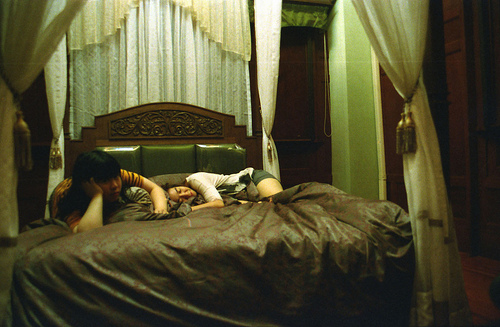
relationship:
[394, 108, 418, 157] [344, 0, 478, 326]
tassel on curtain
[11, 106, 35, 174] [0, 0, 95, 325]
tassel on curtain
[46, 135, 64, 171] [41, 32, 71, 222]
tassel on curtain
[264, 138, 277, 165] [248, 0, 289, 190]
tassel on curtain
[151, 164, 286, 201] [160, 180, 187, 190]
woman has hair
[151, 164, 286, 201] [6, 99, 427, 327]
woman laying on bed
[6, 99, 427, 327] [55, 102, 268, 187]
bed has headboard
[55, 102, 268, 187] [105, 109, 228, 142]
headboard has design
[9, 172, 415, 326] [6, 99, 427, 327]
comforter on bed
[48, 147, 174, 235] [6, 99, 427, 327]
woman laying on bed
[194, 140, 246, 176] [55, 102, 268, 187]
cushion on headboard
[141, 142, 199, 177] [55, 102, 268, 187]
cushion on headboard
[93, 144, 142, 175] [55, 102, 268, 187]
cushion on headboard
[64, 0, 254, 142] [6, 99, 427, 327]
curtain behind bed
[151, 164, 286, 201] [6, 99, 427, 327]
woman on bed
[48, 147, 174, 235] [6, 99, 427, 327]
woman on bed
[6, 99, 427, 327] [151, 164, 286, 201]
bed has woman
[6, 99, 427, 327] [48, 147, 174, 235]
bed has woman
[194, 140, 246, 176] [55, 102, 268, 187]
cushion along headboard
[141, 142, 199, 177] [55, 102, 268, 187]
cushion along headboard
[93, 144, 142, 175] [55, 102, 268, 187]
cushion along headboard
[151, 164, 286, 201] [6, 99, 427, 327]
guy lying in bed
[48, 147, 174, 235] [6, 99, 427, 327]
guy laying on bed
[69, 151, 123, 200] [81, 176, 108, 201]
head in hand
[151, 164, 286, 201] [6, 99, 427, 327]
woman lying in bed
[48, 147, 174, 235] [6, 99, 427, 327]
woman lying in bed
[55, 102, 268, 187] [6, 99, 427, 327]
headboard of bed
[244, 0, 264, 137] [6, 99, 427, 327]
post on a bed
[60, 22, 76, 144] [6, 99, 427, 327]
post on a bed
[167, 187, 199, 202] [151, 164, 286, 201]
face of woman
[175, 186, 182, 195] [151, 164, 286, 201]
eye of woman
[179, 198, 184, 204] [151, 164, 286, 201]
eye of woman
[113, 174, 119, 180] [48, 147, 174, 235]
eye of woman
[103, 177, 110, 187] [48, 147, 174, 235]
eye of woman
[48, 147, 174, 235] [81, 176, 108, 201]
woman leaning on hand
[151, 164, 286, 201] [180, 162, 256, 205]
woman wearing shirt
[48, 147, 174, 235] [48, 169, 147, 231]
woman wearing shirt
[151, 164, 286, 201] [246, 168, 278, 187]
woman wearing shorts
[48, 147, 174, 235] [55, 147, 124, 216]
woman has hair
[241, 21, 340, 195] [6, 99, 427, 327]
door near bed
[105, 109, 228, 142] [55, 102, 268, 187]
design on headboard